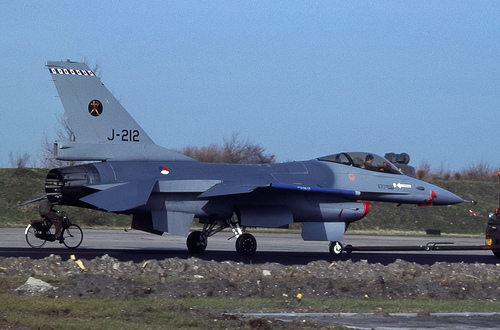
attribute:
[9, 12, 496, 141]
sky — clear, blue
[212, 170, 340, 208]
wing — part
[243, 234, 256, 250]
rim — part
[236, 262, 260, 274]
ground — part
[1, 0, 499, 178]
sky — clear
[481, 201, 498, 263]
car — dark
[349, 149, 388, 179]
pilot — FIGHTER JET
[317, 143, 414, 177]
cockpit — fighter, jet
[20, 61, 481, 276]
jet — gray, fighter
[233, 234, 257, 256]
wheel — part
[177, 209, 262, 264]
wheels — dark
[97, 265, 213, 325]
ground — part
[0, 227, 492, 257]
road — smooth, tarmacked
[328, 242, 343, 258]
wheel — part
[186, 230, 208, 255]
wheel — part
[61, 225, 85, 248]
wheel — part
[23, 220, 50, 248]
wheel — part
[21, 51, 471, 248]
jet — fighter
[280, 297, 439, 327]
ground — part